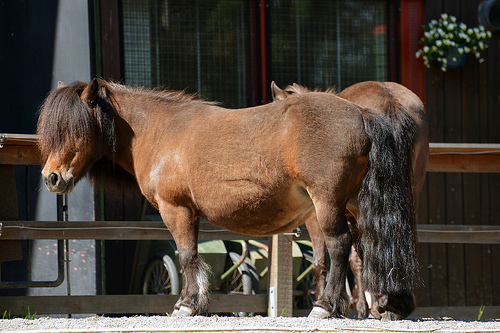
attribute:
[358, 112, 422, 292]
tail — black, long, large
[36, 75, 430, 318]
ponies — small, brown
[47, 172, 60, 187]
nostril — large, dark, round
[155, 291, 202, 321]
hoof — thick, large, grey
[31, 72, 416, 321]
horse — large, brown, hairy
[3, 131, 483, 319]
rail — large, wide, brown, wooden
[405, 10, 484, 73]
plant — large, leafy, green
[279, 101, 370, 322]
leg — large, thick, brown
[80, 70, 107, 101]
ear — large, pointy, brown